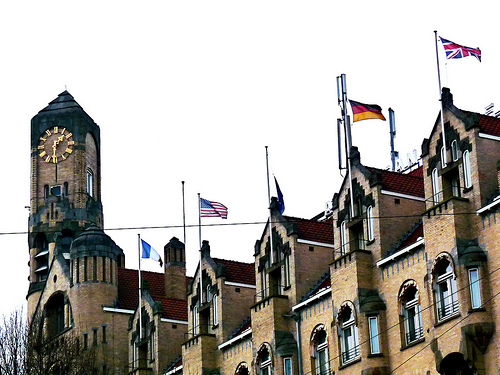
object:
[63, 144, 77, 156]
numerals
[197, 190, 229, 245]
flag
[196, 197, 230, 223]
america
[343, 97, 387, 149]
flag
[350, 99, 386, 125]
germany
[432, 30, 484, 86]
flag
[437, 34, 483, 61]
great britain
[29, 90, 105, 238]
tower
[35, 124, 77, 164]
clock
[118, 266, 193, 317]
tiles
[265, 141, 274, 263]
pole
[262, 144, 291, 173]
no flag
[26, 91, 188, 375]
building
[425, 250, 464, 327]
window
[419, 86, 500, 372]
building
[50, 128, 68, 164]
1:30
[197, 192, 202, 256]
flagpole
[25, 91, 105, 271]
clocktower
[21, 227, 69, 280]
parapet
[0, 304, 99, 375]
tree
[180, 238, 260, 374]
building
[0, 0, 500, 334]
air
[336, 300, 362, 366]
window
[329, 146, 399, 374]
building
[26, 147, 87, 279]
front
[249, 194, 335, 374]
building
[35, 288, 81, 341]
window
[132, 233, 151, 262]
flag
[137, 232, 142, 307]
pole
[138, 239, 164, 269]
american flag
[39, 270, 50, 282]
window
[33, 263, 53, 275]
awning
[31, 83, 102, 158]
stone pillar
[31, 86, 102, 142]
roof